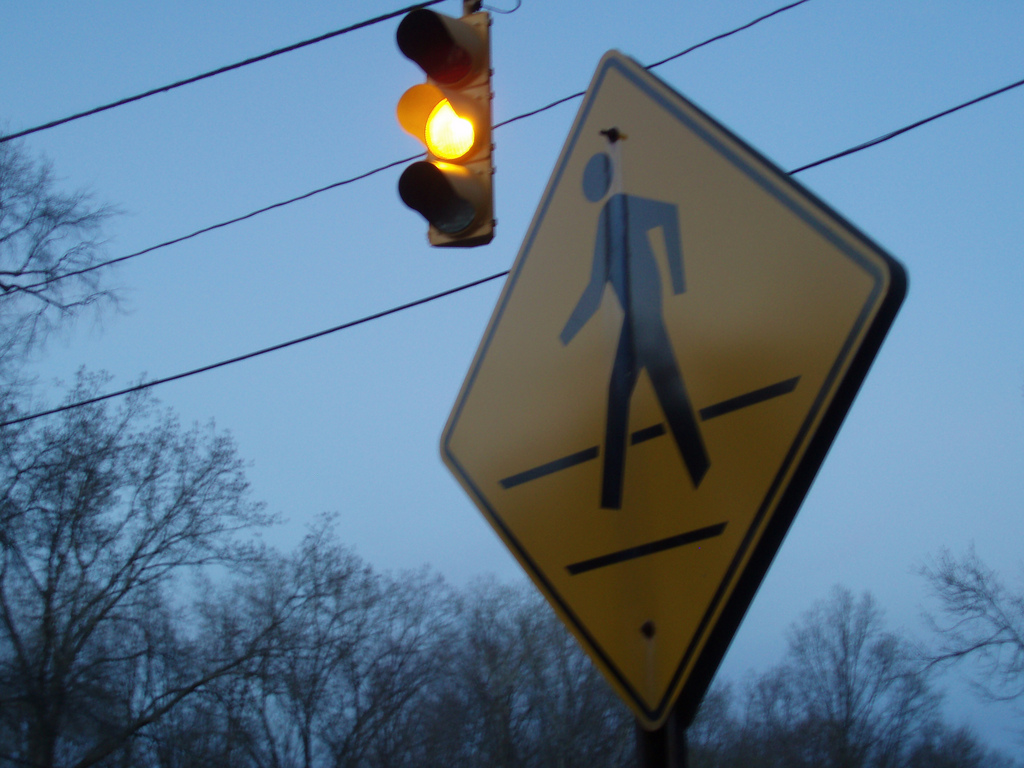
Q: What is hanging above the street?
A: A stoplight that is yellow.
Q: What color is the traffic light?
A: Yellow.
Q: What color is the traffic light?
A: Yellow.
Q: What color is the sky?
A: Blue.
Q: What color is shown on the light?
A: Yellow.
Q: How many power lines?
A: 3.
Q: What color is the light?
A: Yellow.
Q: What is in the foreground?
A: A sign.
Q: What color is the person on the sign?
A: Black.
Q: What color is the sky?
A: Blue.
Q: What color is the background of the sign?
A: Yellow.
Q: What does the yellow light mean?
A: Slow down.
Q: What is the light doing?
A: Hanging.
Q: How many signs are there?
A: One.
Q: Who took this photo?
A: A pedestrian.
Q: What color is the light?
A: It is yellow.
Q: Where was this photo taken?
A: On a sidewalk.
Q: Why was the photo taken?
A: To capture the sign and the light.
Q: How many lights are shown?
A: Just 1.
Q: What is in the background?
A: Trees and the sky.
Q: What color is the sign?
A: It is yellow and black.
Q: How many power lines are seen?
A: There are 3.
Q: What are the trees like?
A: They are bare with no leaves.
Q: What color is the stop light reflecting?
A: Yellow.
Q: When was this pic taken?
A: IN the evening.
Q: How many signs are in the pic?
A: One.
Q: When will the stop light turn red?
A: Next.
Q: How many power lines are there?
A: Three.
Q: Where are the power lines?
A: Behind the stop light.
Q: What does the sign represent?
A: A pedestrian crossing.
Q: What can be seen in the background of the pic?
A: Trees.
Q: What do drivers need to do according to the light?
A: Slow down.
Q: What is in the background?
A: Trees.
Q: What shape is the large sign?
A: Diamond.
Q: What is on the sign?
A: A cross walk sign.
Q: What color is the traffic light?
A: Yellow.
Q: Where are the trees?
A: Next to each other in the background.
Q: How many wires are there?
A: 3.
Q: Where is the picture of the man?
A: On the cross walk sign.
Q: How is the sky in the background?
A: Clear.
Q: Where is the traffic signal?
A: Near the cautionary yellow sign.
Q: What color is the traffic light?
A: Yellow.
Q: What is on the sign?
A: A drawing of a pedestrian.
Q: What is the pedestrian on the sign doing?
A: Walking.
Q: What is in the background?
A: Trees.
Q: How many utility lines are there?
A: 3.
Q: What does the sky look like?
A: Clear.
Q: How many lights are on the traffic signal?
A: 3.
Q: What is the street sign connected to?
A: A pole.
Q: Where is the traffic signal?
A: Close to the yellow sign.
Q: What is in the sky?
A: Three utility type wires.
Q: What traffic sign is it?
A: Pedestrian crossing.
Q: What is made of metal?
A: Square shaped sign.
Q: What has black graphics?
A: Yellow metal sign.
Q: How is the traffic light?
A: The caution light is lit.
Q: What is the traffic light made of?
A: Metal and painted yellow.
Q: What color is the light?
A: Yellow.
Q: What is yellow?
A: The street sign.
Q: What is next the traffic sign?
A: Black wires.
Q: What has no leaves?
A: Trees.